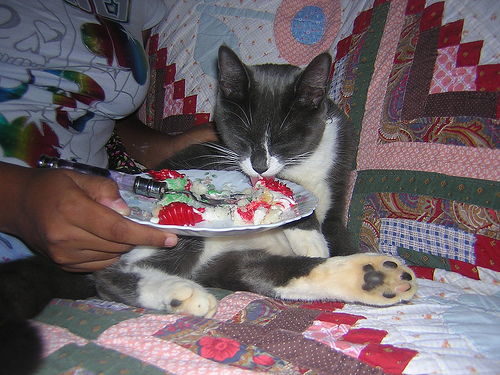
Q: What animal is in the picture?
A: Cat.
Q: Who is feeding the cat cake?
A: A lady.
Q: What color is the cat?
A: Black, white and grey.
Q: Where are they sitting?
A: On a couch.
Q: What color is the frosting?
A: White and red.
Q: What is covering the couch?
A: Quilt.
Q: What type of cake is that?
A: White.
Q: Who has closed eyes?
A: Cat.